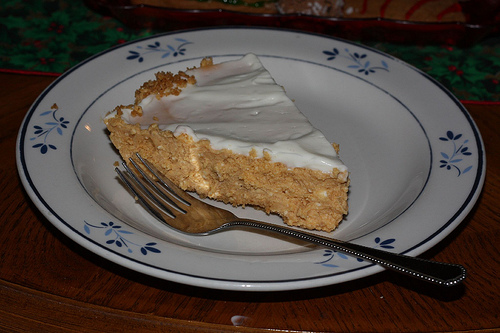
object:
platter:
[122, 0, 479, 46]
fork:
[112, 157, 471, 292]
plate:
[15, 26, 490, 292]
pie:
[96, 51, 350, 231]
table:
[0, 68, 499, 333]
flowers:
[28, 103, 70, 156]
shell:
[118, 72, 208, 108]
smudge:
[227, 314, 246, 327]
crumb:
[49, 103, 60, 110]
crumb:
[113, 160, 121, 166]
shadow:
[380, 276, 467, 303]